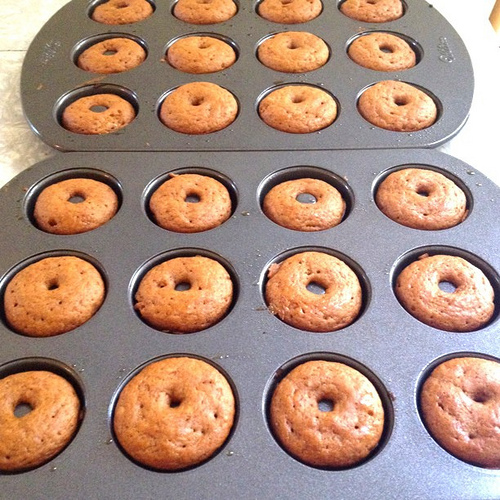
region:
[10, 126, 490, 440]
baking pan full of brown muffins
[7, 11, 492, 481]
muffins in pans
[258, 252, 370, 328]
brown baked muffin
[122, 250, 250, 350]
baked muffin with chocolate in the middle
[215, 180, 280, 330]
muffin crumbs spilled on the pan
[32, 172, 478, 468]
dark grey nonstick pan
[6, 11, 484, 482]
two muffin pans on a counter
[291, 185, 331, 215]
round dot of chocolate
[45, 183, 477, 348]
baked chocolate muffins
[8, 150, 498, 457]
twelve cup muffin pan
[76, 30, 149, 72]
baked cookie in cookie pan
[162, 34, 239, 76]
baked cookie in cookie pan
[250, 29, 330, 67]
baked cookie in cookie pan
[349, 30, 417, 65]
baked cookie in cookie pan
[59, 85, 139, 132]
baked cookie in cookie pan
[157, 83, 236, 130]
baked cookie in cookie pan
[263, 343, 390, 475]
baked cookie in cookie pan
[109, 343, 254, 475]
baked cookie in cookie pan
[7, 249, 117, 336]
baked cookie in cookie pan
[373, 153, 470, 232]
baked cookie in cookie pan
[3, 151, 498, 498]
A donut pan.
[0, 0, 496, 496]
Two pans are in the picture.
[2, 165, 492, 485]
Twelve donuts per pan.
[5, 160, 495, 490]
The donuts are brown.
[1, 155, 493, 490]
The donuts have been cooked.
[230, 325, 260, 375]
The pan is gray.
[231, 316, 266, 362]
The pan is made of metal.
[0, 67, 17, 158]
The table is white.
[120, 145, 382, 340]
The donuts have holes in them.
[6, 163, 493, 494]
Twelve donuts are in the pan.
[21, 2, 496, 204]
Baked goods in pans.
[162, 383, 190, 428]
Small hole in baked good.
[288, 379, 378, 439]
Larger hole in baked good.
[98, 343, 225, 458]
Crumbs on the pan.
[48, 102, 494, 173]
Two pans pushed together.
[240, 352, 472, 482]
Round slot for baked item.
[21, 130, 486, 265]
Row of baked items.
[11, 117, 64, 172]
Table under the pan.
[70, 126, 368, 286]
Silver pan with baked goods.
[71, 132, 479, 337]
Metal pans with baked good in them.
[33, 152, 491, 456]
Baked goods in a pan.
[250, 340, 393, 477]
Hole in the baked good.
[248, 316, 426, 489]
Circular pan with baked good.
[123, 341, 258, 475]
Brown baked good in pan.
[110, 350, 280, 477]
Small hole in a baked good.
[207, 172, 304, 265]
Crumbs on the pan.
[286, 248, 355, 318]
Larger hole in the baked good.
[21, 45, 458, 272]
Two pans pushed together.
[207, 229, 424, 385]
Metal pan on the table.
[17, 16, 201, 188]
Table under the pan.